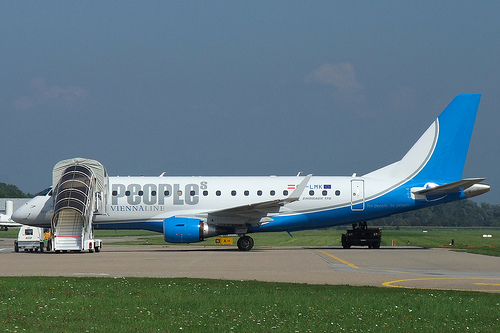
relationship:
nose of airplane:
[10, 190, 38, 227] [2, 92, 489, 254]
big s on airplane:
[199, 180, 209, 189] [9, 109, 468, 269]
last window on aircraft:
[333, 187, 342, 198] [12, 93, 491, 252]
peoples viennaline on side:
[111, 181, 207, 211] [103, 180, 278, 213]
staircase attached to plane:
[45, 146, 110, 270] [7, 129, 477, 255]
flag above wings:
[285, 179, 300, 191] [227, 173, 318, 230]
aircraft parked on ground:
[12, 93, 491, 252] [0, 234, 500, 293]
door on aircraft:
[347, 175, 368, 212] [12, 93, 491, 252]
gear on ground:
[237, 236, 255, 251] [0, 235, 500, 292]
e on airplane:
[127, 184, 141, 205] [2, 92, 489, 254]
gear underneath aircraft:
[227, 224, 267, 259] [12, 93, 491, 252]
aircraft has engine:
[12, 93, 491, 252] [160, 211, 205, 239]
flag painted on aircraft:
[288, 184, 295, 188] [12, 93, 491, 252]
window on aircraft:
[122, 189, 130, 197] [12, 93, 491, 252]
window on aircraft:
[163, 189, 170, 197] [12, 93, 491, 252]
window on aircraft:
[188, 187, 197, 197] [12, 93, 491, 252]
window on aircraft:
[225, 187, 237, 196] [12, 93, 491, 252]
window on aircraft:
[256, 189, 261, 197] [12, 93, 491, 252]